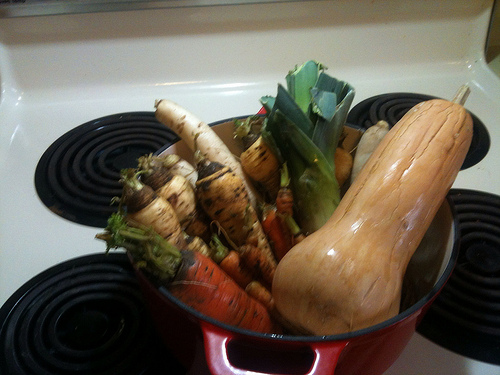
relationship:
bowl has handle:
[110, 104, 459, 370] [192, 323, 343, 374]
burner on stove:
[35, 112, 193, 231] [3, 13, 499, 369]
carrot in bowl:
[131, 222, 287, 333] [110, 104, 459, 370]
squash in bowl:
[262, 80, 482, 333] [110, 104, 459, 370]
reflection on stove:
[160, 62, 268, 102] [3, 13, 499, 369]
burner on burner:
[35, 112, 193, 231] [35, 112, 193, 231]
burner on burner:
[352, 87, 492, 169] [35, 112, 193, 231]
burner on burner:
[6, 240, 206, 373] [35, 112, 193, 231]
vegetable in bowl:
[278, 83, 471, 330] [110, 104, 459, 370]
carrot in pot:
[131, 222, 287, 333] [115, 107, 461, 373]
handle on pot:
[192, 323, 343, 374] [115, 107, 461, 373]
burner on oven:
[31, 107, 193, 231] [5, 6, 493, 373]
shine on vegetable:
[322, 220, 376, 279] [278, 83, 471, 330]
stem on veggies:
[266, 58, 357, 205] [279, 202, 304, 240]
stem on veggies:
[266, 58, 357, 205] [446, 79, 471, 107]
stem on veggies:
[266, 58, 357, 205] [100, 210, 180, 282]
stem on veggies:
[266, 58, 357, 205] [269, 151, 296, 188]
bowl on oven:
[110, 104, 459, 370] [5, 6, 493, 373]